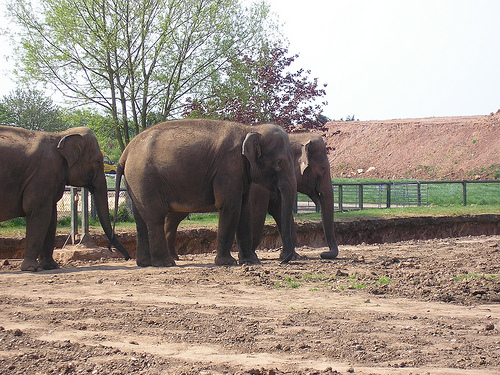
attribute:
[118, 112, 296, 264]
elephant — brown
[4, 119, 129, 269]
elephant — slightly behind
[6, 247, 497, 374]
dirt — dry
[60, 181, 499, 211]
fence — gray, metal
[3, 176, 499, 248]
grass — small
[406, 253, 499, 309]
dirt — piled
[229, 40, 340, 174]
tree — small, reddish, red, green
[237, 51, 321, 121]
leaves — purplish red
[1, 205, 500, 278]
ditch — small, cylindrical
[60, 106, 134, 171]
tree — green, tall, leafy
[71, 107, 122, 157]
leaves — yellowish green, green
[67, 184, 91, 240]
posts — metal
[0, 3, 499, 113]
sky — pale blue, grey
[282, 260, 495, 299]
grass — green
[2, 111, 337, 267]
elephants — together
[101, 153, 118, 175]
vehicle — yellow